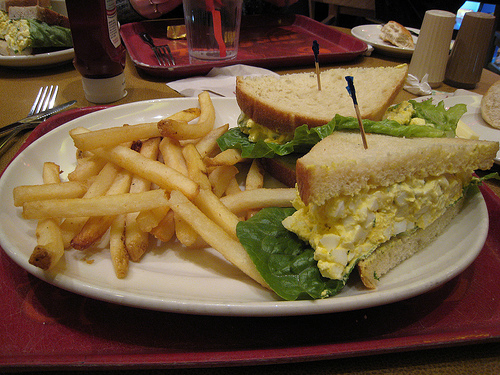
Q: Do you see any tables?
A: Yes, there is a table.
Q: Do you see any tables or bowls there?
A: Yes, there is a table.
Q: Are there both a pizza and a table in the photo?
A: No, there is a table but no pizzas.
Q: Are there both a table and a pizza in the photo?
A: No, there is a table but no pizzas.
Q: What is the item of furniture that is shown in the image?
A: The piece of furniture is a table.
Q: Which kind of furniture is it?
A: The piece of furniture is a table.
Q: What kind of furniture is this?
A: This is a table.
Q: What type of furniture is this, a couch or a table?
A: This is a table.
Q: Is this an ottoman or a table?
A: This is a table.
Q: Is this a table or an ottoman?
A: This is a table.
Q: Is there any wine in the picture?
A: No, there is no wine.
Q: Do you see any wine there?
A: No, there is no wine.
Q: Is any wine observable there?
A: No, there is no wine.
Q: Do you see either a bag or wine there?
A: No, there are no wine or bags.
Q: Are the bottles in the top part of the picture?
A: Yes, the bottles are in the top of the image.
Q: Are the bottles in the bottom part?
A: No, the bottles are in the top of the image.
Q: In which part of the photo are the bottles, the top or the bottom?
A: The bottles are in the top of the image.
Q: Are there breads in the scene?
A: Yes, there is a bread.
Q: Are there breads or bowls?
A: Yes, there is a bread.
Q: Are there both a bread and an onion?
A: No, there is a bread but no onions.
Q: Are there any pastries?
A: No, there are no pastries.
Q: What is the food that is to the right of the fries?
A: The food is a bread.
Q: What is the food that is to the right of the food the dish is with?
A: The food is a bread.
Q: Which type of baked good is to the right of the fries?
A: The food is a bread.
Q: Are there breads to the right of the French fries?
A: Yes, there is a bread to the right of the French fries.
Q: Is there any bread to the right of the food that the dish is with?
A: Yes, there is a bread to the right of the French fries.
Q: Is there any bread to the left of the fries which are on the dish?
A: No, the bread is to the right of the French fries.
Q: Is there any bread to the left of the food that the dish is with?
A: No, the bread is to the right of the French fries.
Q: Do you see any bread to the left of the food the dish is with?
A: No, the bread is to the right of the French fries.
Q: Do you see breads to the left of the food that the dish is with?
A: No, the bread is to the right of the French fries.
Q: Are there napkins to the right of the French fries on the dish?
A: No, there is a bread to the right of the French fries.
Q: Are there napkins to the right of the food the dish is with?
A: No, there is a bread to the right of the French fries.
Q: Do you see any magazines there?
A: No, there are no magazines.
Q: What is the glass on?
A: The glass is on the tray.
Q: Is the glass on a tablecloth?
A: No, the glass is on the tray.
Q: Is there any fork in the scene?
A: Yes, there is a fork.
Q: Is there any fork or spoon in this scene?
A: Yes, there is a fork.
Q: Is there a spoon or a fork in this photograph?
A: Yes, there is a fork.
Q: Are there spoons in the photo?
A: No, there are no spoons.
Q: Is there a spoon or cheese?
A: No, there are no spoons or cheese.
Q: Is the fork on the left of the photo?
A: Yes, the fork is on the left of the image.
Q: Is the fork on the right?
A: No, the fork is on the left of the image.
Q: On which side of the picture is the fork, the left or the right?
A: The fork is on the left of the image.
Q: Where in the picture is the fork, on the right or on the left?
A: The fork is on the left of the image.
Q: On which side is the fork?
A: The fork is on the left of the image.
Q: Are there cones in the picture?
A: No, there are no cones.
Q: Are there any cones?
A: No, there are no cones.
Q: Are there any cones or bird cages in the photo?
A: No, there are no cones or bird cages.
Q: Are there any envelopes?
A: No, there are no envelopes.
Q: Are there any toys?
A: No, there are no toys.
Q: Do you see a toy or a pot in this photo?
A: No, there are no toys or pots.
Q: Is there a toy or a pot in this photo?
A: No, there are no toys or pots.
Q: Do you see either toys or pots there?
A: No, there are no toys or pots.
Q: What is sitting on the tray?
A: The dish is sitting on the tray.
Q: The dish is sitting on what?
A: The dish is sitting on the tray.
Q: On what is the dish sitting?
A: The dish is sitting on the tray.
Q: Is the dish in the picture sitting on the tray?
A: Yes, the dish is sitting on the tray.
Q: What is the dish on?
A: The dish is on the tray.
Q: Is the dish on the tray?
A: Yes, the dish is on the tray.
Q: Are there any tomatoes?
A: No, there are no tomatoes.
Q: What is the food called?
A: The food is fries.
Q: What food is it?
A: The food is fries.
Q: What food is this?
A: These are fries.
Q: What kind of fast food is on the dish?
A: The food is fries.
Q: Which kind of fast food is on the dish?
A: The food is fries.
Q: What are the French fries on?
A: The French fries are on the dish.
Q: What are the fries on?
A: The French fries are on the dish.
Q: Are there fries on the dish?
A: Yes, there are fries on the dish.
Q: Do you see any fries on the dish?
A: Yes, there are fries on the dish.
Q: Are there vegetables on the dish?
A: No, there are fries on the dish.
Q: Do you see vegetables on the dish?
A: No, there are fries on the dish.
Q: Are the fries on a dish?
A: Yes, the fries are on a dish.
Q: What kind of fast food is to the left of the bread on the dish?
A: The food is fries.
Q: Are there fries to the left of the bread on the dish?
A: Yes, there are fries to the left of the bread.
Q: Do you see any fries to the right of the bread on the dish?
A: No, the fries are to the left of the bread.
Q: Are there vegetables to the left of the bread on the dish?
A: No, there are fries to the left of the bread.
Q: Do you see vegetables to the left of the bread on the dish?
A: No, there are fries to the left of the bread.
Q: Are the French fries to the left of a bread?
A: Yes, the French fries are to the left of a bread.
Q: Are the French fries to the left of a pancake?
A: No, the French fries are to the left of a bread.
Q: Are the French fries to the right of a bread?
A: No, the French fries are to the left of a bread.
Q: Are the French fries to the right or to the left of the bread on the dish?
A: The French fries are to the left of the bread.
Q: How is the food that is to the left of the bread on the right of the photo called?
A: The food is fries.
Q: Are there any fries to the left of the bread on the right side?
A: Yes, there are fries to the left of the bread.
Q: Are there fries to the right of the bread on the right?
A: No, the fries are to the left of the bread.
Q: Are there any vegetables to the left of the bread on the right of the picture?
A: No, there are fries to the left of the bread.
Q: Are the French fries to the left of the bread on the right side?
A: Yes, the French fries are to the left of the bread.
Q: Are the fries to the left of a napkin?
A: No, the fries are to the left of the bread.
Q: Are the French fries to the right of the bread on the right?
A: No, the French fries are to the left of the bread.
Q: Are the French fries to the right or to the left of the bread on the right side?
A: The French fries are to the left of the bread.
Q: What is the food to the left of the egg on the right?
A: The food is fries.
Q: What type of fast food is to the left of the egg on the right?
A: The food is fries.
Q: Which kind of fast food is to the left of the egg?
A: The food is fries.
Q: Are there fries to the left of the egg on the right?
A: Yes, there are fries to the left of the egg.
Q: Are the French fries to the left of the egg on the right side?
A: Yes, the French fries are to the left of the egg.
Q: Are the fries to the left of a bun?
A: No, the fries are to the left of the egg.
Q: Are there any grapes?
A: No, there are no grapes.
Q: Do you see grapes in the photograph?
A: No, there are no grapes.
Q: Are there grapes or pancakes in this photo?
A: No, there are no grapes or pancakes.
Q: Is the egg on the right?
A: Yes, the egg is on the right of the image.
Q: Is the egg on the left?
A: No, the egg is on the right of the image.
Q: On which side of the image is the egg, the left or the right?
A: The egg is on the right of the image.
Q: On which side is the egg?
A: The egg is on the right of the image.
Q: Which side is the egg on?
A: The egg is on the right of the image.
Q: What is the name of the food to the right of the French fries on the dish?
A: The food is an egg.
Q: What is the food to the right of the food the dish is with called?
A: The food is an egg.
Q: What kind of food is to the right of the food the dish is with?
A: The food is an egg.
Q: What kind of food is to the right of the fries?
A: The food is an egg.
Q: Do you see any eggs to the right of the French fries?
A: Yes, there is an egg to the right of the French fries.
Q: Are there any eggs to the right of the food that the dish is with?
A: Yes, there is an egg to the right of the French fries.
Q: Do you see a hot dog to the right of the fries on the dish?
A: No, there is an egg to the right of the French fries.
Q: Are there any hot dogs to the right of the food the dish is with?
A: No, there is an egg to the right of the French fries.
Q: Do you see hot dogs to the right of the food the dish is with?
A: No, there is an egg to the right of the French fries.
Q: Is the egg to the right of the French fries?
A: Yes, the egg is to the right of the French fries.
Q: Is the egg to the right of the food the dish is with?
A: Yes, the egg is to the right of the French fries.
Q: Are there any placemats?
A: No, there are no placemats.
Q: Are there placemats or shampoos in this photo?
A: No, there are no placemats or shampoos.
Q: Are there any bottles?
A: Yes, there is a bottle.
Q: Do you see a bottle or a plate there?
A: Yes, there is a bottle.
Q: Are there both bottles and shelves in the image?
A: No, there is a bottle but no shelves.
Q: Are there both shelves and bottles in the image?
A: No, there is a bottle but no shelves.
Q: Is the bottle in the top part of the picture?
A: Yes, the bottle is in the top of the image.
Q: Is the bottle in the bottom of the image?
A: No, the bottle is in the top of the image.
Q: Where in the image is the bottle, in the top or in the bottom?
A: The bottle is in the top of the image.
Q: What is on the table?
A: The bottle is on the table.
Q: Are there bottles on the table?
A: Yes, there is a bottle on the table.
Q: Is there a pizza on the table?
A: No, there is a bottle on the table.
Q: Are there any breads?
A: Yes, there is a bread.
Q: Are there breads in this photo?
A: Yes, there is a bread.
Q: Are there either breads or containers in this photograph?
A: Yes, there is a bread.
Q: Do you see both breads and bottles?
A: Yes, there are both a bread and a bottle.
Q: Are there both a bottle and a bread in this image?
A: Yes, there are both a bread and a bottle.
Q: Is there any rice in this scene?
A: No, there is no rice.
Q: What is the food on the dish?
A: The food is a bread.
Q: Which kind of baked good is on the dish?
A: The food is a bread.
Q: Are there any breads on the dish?
A: Yes, there is a bread on the dish.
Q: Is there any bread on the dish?
A: Yes, there is a bread on the dish.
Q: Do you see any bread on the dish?
A: Yes, there is a bread on the dish.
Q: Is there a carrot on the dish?
A: No, there is a bread on the dish.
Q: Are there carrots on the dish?
A: No, there is a bread on the dish.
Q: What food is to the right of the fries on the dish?
A: The food is a bread.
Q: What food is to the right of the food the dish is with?
A: The food is a bread.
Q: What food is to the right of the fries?
A: The food is a bread.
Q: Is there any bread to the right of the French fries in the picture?
A: Yes, there is a bread to the right of the French fries.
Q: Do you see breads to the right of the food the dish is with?
A: Yes, there is a bread to the right of the French fries.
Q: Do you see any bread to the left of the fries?
A: No, the bread is to the right of the fries.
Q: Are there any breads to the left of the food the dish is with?
A: No, the bread is to the right of the fries.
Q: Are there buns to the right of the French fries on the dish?
A: No, there is a bread to the right of the fries.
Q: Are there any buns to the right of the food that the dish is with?
A: No, there is a bread to the right of the fries.